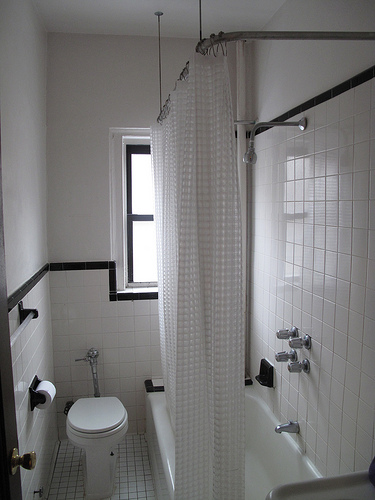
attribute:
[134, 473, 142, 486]
tiles — white, small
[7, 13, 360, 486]
bathroom — clean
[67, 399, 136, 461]
toilet — white, very white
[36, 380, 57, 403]
paper — full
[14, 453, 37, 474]
knob — brass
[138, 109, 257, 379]
curtain — white, vinyl, transparent, plastic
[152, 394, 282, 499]
bathtub — white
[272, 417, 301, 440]
nozzle — silver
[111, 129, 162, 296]
window — glass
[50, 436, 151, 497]
floor — tiled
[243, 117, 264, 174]
shower head — chrome, silver metal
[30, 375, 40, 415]
paper roll holder — black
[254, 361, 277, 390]
soap holder — black, porcelain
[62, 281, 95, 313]
tile — white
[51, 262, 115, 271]
tiles — black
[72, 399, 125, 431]
toilet lid — white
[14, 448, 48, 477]
nob — gold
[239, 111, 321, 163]
shower bar — steel, metal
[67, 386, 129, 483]
bathroom toilet — white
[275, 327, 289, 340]
fixture — silver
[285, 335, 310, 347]
fixture — metal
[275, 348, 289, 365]
fixture — metal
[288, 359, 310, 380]
fixture — metal